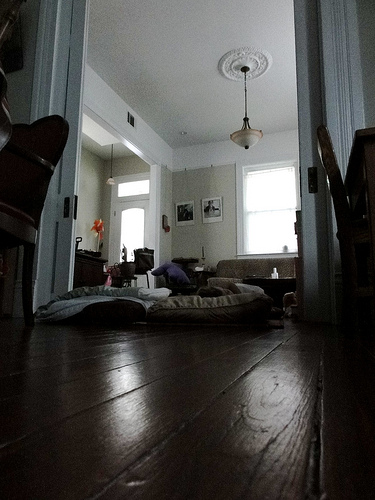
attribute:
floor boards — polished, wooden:
[2, 329, 372, 497]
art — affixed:
[174, 199, 195, 226]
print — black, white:
[202, 194, 224, 222]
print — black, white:
[174, 198, 194, 224]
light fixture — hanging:
[215, 46, 274, 153]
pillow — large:
[147, 291, 270, 324]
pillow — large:
[33, 285, 172, 325]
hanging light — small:
[108, 145, 121, 188]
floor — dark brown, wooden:
[16, 325, 373, 492]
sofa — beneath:
[212, 262, 299, 292]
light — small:
[105, 144, 115, 184]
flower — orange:
[87, 216, 104, 252]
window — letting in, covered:
[233, 157, 303, 260]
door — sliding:
[290, 0, 327, 335]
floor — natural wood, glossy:
[6, 303, 366, 495]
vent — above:
[125, 111, 136, 129]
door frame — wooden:
[72, 106, 155, 288]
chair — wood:
[2, 74, 73, 334]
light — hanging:
[229, 66, 265, 150]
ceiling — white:
[86, 1, 298, 148]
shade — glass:
[231, 126, 264, 149]